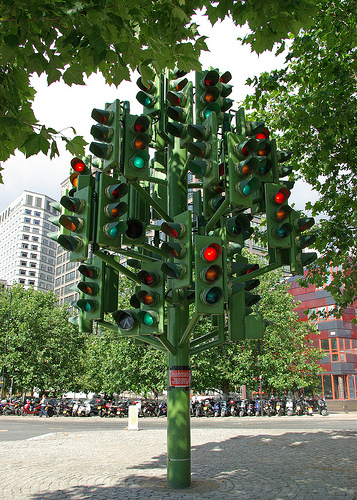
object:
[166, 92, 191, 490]
pole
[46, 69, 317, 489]
light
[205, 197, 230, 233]
pole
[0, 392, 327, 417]
bikes